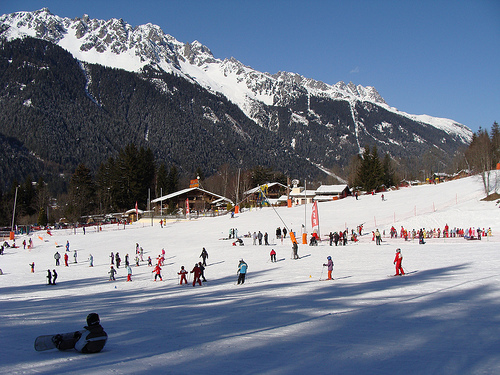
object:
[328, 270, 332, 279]
red pants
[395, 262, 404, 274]
red pants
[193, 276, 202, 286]
red pants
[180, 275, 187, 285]
red pants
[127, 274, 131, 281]
red pants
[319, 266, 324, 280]
ski pole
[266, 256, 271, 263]
ski pole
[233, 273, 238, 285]
ski pole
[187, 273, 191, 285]
ski pole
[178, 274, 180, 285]
ski pole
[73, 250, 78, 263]
person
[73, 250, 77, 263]
person standing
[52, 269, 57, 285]
people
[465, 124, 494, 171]
trees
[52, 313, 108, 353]
man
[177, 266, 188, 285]
people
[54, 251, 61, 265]
people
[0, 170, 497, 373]
snow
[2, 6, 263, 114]
snow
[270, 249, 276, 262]
person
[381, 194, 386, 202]
man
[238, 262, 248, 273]
jacket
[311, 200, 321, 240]
flag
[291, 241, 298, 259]
person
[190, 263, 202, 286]
people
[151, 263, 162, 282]
people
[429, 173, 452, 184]
cabin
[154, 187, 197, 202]
snow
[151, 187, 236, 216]
brown cabin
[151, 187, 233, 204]
roof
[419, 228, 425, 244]
standing person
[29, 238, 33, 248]
standing person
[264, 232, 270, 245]
standing person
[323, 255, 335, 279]
people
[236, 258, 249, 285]
people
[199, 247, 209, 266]
people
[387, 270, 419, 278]
snowboard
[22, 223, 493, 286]
group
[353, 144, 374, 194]
tree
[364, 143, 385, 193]
tree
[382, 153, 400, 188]
tree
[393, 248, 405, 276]
person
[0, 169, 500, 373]
ski slope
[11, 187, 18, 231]
pole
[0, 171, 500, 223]
hill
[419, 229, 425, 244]
people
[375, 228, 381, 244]
people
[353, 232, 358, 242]
people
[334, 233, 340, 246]
people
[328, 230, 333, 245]
people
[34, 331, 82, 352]
snowboard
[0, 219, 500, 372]
ground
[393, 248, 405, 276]
giraffe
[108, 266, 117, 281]
people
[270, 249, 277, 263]
people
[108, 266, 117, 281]
person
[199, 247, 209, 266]
person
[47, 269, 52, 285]
person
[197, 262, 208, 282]
person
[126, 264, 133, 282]
person